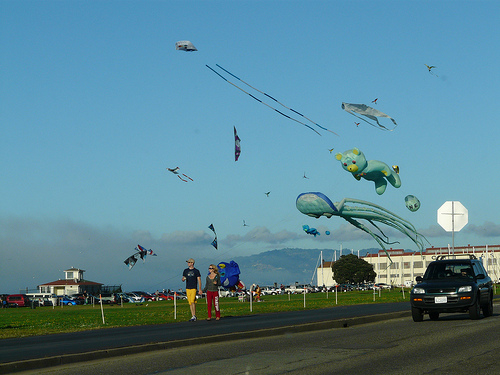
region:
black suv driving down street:
[398, 241, 497, 328]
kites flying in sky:
[120, 26, 440, 270]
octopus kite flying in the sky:
[286, 184, 446, 269]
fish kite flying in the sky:
[330, 83, 405, 139]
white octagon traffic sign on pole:
[434, 193, 472, 240]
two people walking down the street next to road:
[170, 251, 232, 326]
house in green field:
[32, 257, 104, 303]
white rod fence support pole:
[90, 289, 121, 326]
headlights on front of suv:
[409, 278, 476, 298]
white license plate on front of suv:
[430, 293, 450, 312]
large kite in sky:
[334, 144, 414, 201]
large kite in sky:
[204, 214, 226, 267]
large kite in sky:
[129, 240, 160, 267]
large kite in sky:
[159, 163, 201, 195]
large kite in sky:
[229, 124, 251, 166]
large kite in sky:
[259, 191, 276, 205]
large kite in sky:
[342, 98, 402, 141]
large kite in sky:
[398, 188, 427, 210]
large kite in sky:
[296, 223, 331, 243]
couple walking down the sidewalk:
[181, 257, 222, 321]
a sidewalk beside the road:
[5, 298, 410, 369]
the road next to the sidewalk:
[15, 305, 496, 374]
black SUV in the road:
[410, 253, 492, 316]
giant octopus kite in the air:
[295, 190, 432, 264]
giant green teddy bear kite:
[334, 148, 400, 194]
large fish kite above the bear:
[341, 102, 397, 129]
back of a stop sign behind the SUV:
[435, 199, 468, 257]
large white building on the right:
[308, 246, 498, 285]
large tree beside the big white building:
[332, 255, 377, 287]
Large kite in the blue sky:
[333, 82, 414, 147]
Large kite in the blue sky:
[328, 130, 411, 189]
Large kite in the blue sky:
[399, 54, 449, 93]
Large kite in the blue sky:
[400, 191, 447, 232]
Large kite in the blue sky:
[288, 158, 321, 185]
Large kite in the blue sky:
[253, 186, 279, 209]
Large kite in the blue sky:
[235, 208, 253, 238]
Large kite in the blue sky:
[190, 216, 232, 254]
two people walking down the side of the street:
[173, 253, 315, 328]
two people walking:
[179, 257, 244, 327]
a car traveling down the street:
[411, 249, 495, 334]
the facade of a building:
[311, 249, 498, 290]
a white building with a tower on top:
[35, 262, 107, 304]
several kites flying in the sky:
[79, 27, 429, 272]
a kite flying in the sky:
[172, 39, 199, 57]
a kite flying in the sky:
[161, 161, 198, 188]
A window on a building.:
[381, 262, 388, 268]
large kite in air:
[209, 124, 251, 176]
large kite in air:
[285, 190, 361, 240]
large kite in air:
[317, 79, 379, 119]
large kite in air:
[149, 14, 219, 77]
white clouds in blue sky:
[106, 190, 137, 205]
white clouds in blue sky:
[47, 229, 68, 246]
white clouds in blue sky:
[12, 260, 33, 277]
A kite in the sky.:
[116, 241, 154, 268]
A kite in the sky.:
[168, 165, 191, 182]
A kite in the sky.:
[226, 120, 240, 163]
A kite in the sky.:
[173, 37, 200, 57]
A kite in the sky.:
[331, 97, 401, 129]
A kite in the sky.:
[403, 195, 419, 211]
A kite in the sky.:
[299, 194, 429, 261]